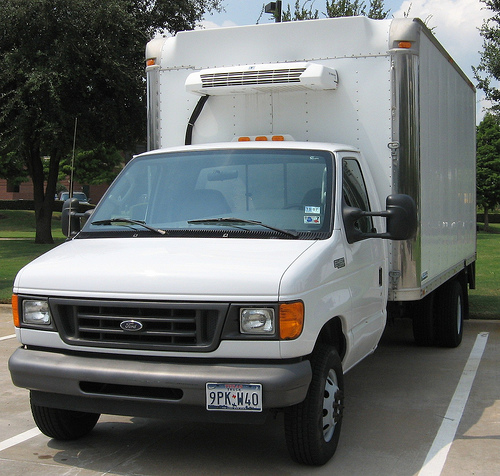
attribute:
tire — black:
[320, 369, 349, 450]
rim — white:
[328, 382, 346, 432]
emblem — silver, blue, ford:
[115, 314, 144, 336]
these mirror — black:
[383, 196, 412, 238]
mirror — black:
[58, 202, 81, 224]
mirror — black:
[205, 168, 238, 186]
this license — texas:
[204, 385, 267, 413]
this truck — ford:
[34, 254, 312, 392]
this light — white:
[241, 309, 271, 333]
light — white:
[21, 296, 50, 328]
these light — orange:
[278, 304, 299, 328]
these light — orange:
[10, 296, 29, 325]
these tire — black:
[447, 303, 461, 333]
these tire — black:
[409, 314, 430, 341]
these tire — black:
[28, 397, 82, 429]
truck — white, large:
[144, 45, 472, 363]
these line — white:
[442, 365, 466, 471]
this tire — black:
[310, 353, 336, 448]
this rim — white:
[324, 395, 340, 427]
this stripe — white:
[6, 435, 33, 445]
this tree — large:
[19, 34, 71, 235]